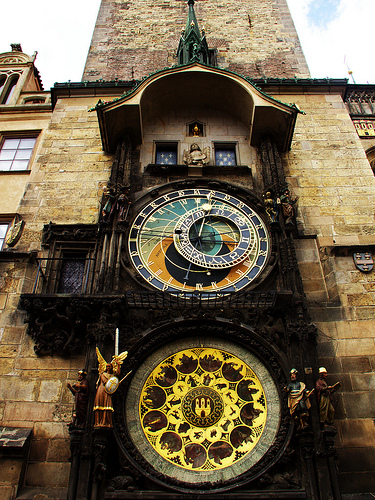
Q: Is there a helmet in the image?
A: No, there are no helmets.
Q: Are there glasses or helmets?
A: No, there are no helmets or glasses.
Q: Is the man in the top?
A: Yes, the man is in the top of the image.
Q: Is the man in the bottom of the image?
A: No, the man is in the top of the image.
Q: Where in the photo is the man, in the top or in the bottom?
A: The man is in the top of the image.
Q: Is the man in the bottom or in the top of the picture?
A: The man is in the top of the image.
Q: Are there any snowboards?
A: No, there are no snowboards.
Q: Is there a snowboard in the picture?
A: No, there are no snowboards.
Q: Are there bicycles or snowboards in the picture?
A: No, there are no snowboards or bicycles.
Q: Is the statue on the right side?
A: Yes, the statue is on the right of the image.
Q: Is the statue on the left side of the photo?
A: No, the statue is on the right of the image.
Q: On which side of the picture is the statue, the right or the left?
A: The statue is on the right of the image.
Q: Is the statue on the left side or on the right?
A: The statue is on the right of the image.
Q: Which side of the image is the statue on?
A: The statue is on the right of the image.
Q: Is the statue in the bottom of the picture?
A: Yes, the statue is in the bottom of the image.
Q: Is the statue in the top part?
A: No, the statue is in the bottom of the image.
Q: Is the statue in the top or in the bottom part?
A: The statue is in the bottom of the image.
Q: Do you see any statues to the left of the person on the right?
A: Yes, there is a statue to the left of the person.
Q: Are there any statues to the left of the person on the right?
A: Yes, there is a statue to the left of the person.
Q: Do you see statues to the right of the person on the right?
A: No, the statue is to the left of the person.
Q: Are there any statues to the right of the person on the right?
A: No, the statue is to the left of the person.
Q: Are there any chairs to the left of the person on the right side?
A: No, there is a statue to the left of the person.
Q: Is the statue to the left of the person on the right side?
A: Yes, the statue is to the left of the person.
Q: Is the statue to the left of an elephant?
A: No, the statue is to the left of the person.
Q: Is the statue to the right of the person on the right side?
A: No, the statue is to the left of the person.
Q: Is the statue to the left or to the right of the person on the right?
A: The statue is to the left of the person.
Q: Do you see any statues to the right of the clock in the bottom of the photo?
A: Yes, there is a statue to the right of the clock.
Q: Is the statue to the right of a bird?
A: No, the statue is to the right of the clock.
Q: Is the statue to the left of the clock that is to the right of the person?
A: No, the statue is to the right of the clock.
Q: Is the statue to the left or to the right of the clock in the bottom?
A: The statue is to the right of the clock.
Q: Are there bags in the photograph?
A: No, there are no bags.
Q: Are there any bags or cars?
A: No, there are no bags or cars.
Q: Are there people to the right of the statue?
A: Yes, there is a person to the right of the statue.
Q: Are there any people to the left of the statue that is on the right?
A: No, the person is to the right of the statue.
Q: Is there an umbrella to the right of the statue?
A: No, there is a person to the right of the statue.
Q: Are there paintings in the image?
A: No, there are no paintings.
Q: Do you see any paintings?
A: No, there are no paintings.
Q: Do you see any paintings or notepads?
A: No, there are no paintings or notepads.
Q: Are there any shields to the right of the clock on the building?
A: Yes, there is a shield to the right of the clock.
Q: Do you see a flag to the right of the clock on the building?
A: No, there is a shield to the right of the clock.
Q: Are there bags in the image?
A: No, there are no bags.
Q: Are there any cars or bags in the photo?
A: No, there are no bags or cars.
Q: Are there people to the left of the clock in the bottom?
A: Yes, there is a person to the left of the clock.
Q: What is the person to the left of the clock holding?
A: The person is holding the shield.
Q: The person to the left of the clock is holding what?
A: The person is holding the shield.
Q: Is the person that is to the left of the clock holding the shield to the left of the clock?
A: Yes, the person is holding the shield.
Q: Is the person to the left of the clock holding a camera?
A: No, the person is holding the shield.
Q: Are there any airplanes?
A: No, there are no airplanes.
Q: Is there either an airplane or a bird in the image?
A: No, there are no airplanes or birds.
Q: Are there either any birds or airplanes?
A: No, there are no airplanes or birds.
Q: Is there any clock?
A: Yes, there is a clock.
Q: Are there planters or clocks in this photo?
A: Yes, there is a clock.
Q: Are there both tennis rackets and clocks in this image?
A: No, there is a clock but no rackets.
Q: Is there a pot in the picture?
A: No, there are no pots.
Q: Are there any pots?
A: No, there are no pots.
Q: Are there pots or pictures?
A: No, there are no pots or pictures.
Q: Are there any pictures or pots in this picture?
A: No, there are no pots or pictures.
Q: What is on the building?
A: The clock is on the building.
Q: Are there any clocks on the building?
A: Yes, there is a clock on the building.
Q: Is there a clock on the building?
A: Yes, there is a clock on the building.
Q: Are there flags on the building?
A: No, there is a clock on the building.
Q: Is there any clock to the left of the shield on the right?
A: Yes, there is a clock to the left of the shield.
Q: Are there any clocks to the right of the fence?
A: Yes, there is a clock to the right of the fence.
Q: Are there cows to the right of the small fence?
A: No, there is a clock to the right of the fence.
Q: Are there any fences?
A: Yes, there is a fence.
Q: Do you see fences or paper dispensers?
A: Yes, there is a fence.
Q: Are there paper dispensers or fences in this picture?
A: Yes, there is a fence.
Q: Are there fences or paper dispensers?
A: Yes, there is a fence.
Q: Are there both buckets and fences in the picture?
A: No, there is a fence but no buckets.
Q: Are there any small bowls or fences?
A: Yes, there is a small fence.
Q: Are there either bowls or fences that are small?
A: Yes, the fence is small.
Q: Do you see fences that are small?
A: Yes, there is a small fence.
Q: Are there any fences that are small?
A: Yes, there is a fence that is small.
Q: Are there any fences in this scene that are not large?
A: Yes, there is a small fence.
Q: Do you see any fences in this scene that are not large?
A: Yes, there is a small fence.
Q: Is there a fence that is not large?
A: Yes, there is a small fence.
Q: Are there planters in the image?
A: No, there are no planters.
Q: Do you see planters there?
A: No, there are no planters.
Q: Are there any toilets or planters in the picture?
A: No, there are no planters or toilets.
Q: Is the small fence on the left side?
A: Yes, the fence is on the left of the image.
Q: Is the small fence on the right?
A: No, the fence is on the left of the image.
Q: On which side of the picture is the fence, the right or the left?
A: The fence is on the left of the image.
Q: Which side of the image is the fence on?
A: The fence is on the left of the image.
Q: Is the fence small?
A: Yes, the fence is small.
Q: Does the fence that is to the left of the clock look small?
A: Yes, the fence is small.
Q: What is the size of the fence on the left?
A: The fence is small.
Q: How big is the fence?
A: The fence is small.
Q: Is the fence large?
A: No, the fence is small.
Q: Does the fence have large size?
A: No, the fence is small.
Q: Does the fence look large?
A: No, the fence is small.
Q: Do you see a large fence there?
A: No, there is a fence but it is small.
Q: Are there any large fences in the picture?
A: No, there is a fence but it is small.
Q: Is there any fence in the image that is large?
A: No, there is a fence but it is small.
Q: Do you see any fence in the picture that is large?
A: No, there is a fence but it is small.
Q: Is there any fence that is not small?
A: No, there is a fence but it is small.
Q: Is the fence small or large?
A: The fence is small.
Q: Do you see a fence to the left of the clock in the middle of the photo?
A: Yes, there is a fence to the left of the clock.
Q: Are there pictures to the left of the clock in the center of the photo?
A: No, there is a fence to the left of the clock.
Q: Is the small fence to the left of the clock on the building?
A: Yes, the fence is to the left of the clock.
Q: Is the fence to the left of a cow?
A: No, the fence is to the left of the clock.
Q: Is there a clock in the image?
A: Yes, there is a clock.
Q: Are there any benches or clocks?
A: Yes, there is a clock.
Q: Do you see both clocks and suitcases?
A: No, there is a clock but no suitcases.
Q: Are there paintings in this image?
A: No, there are no paintings.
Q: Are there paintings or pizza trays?
A: No, there are no paintings or pizza trays.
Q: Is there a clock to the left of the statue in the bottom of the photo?
A: Yes, there is a clock to the left of the statue.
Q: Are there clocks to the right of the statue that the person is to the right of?
A: No, the clock is to the left of the statue.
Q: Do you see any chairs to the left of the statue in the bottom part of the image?
A: No, there is a clock to the left of the statue.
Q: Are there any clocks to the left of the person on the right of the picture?
A: Yes, there is a clock to the left of the person.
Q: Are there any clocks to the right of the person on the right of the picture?
A: No, the clock is to the left of the person.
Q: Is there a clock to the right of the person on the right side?
A: No, the clock is to the left of the person.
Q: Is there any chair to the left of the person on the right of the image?
A: No, there is a clock to the left of the person.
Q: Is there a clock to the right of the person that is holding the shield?
A: Yes, there is a clock to the right of the person.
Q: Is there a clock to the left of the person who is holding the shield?
A: No, the clock is to the right of the person.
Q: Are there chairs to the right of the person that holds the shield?
A: No, there is a clock to the right of the person.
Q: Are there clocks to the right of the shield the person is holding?
A: Yes, there is a clock to the right of the shield.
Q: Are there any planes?
A: No, there are no planes.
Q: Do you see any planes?
A: No, there are no planes.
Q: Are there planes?
A: No, there are no planes.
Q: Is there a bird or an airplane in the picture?
A: No, there are no airplanes or birds.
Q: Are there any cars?
A: No, there are no cars.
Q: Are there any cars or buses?
A: No, there are no cars or buses.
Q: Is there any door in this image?
A: Yes, there is a door.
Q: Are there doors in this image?
A: Yes, there is a door.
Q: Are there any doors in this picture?
A: Yes, there is a door.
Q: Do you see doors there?
A: Yes, there is a door.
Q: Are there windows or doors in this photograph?
A: Yes, there is a door.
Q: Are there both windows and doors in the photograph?
A: Yes, there are both a door and a window.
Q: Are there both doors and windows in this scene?
A: Yes, there are both a door and a window.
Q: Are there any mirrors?
A: No, there are no mirrors.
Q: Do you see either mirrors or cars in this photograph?
A: No, there are no mirrors or cars.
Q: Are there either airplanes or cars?
A: No, there are no cars or airplanes.